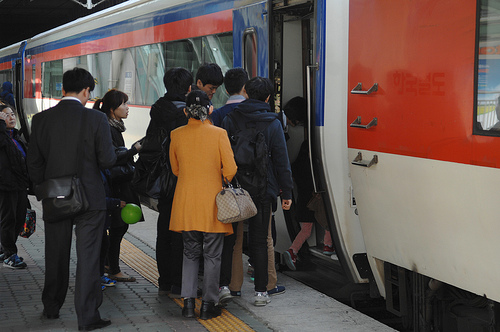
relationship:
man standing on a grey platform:
[25, 66, 119, 327] [6, 200, 401, 329]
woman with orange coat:
[157, 91, 233, 321] [164, 116, 235, 237]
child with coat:
[92, 90, 141, 283] [107, 119, 144, 216]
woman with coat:
[3, 100, 39, 271] [1, 126, 31, 198]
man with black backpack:
[212, 77, 294, 306] [224, 111, 274, 191]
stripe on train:
[26, 0, 233, 55] [3, 1, 484, 322]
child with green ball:
[105, 156, 144, 293] [119, 201, 140, 226]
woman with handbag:
[168, 90, 236, 318] [215, 174, 257, 223]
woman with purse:
[0, 101, 30, 272] [18, 199, 40, 243]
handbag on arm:
[215, 174, 257, 223] [214, 125, 237, 184]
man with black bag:
[25, 66, 119, 327] [34, 170, 87, 227]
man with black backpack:
[223, 75, 298, 306] [224, 115, 278, 204]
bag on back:
[34, 170, 87, 227] [25, 107, 105, 215]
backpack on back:
[224, 115, 278, 204] [227, 107, 279, 189]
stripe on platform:
[114, 231, 252, 330] [6, 200, 401, 329]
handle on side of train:
[351, 82, 378, 94] [3, 1, 484, 322]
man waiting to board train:
[25, 66, 119, 327] [3, 1, 484, 322]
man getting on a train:
[25, 66, 119, 327] [3, 1, 484, 322]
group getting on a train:
[0, 64, 295, 331] [3, 1, 484, 322]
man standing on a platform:
[25, 66, 119, 327] [0, 201, 399, 332]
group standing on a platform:
[0, 64, 295, 331] [0, 201, 399, 332]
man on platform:
[25, 66, 119, 327] [0, 201, 399, 332]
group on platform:
[0, 64, 295, 331] [0, 201, 399, 332]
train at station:
[0, 0, 499, 332] [2, 6, 484, 331]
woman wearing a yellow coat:
[168, 90, 236, 318] [168, 120, 238, 233]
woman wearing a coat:
[168, 90, 236, 318] [107, 119, 145, 226]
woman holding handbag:
[168, 90, 236, 318] [215, 174, 257, 223]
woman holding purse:
[0, 101, 30, 272] [15, 204, 41, 245]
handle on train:
[349, 81, 379, 100] [3, 1, 484, 322]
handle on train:
[344, 109, 379, 132] [3, 1, 484, 322]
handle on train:
[350, 146, 380, 167] [3, 1, 484, 322]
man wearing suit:
[23, 64, 125, 327] [29, 91, 117, 326]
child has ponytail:
[92, 90, 141, 283] [85, 85, 125, 118]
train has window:
[3, 1, 484, 322] [28, 31, 240, 115]